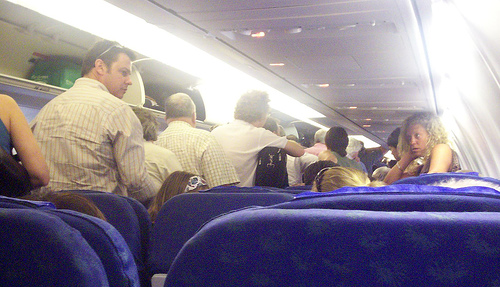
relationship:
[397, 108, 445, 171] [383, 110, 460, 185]
hair on woman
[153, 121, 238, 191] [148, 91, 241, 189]
shirt on passenger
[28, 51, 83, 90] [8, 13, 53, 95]
luggage on compartment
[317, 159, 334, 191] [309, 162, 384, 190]
headband on head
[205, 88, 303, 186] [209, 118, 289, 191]
man wearing white shirt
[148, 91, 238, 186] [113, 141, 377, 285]
passenger standing in aisle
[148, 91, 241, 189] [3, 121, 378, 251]
passenger standing in isle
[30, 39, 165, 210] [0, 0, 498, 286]
man on aircraft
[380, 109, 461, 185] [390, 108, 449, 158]
woman resting her head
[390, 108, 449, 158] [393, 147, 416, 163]
head on hand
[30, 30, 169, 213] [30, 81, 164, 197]
man with shirt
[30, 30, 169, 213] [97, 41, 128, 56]
man with sunglasses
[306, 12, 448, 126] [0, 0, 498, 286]
storage on a aircraft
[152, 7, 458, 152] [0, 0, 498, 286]
compartments on a aircraft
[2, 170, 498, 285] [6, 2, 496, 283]
seats on a airliner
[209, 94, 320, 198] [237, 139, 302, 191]
man with luggage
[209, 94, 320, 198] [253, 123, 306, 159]
man with arm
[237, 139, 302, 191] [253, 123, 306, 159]
luggage under arm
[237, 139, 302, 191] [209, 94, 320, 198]
luggage under man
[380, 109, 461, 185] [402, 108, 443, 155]
woman scratching head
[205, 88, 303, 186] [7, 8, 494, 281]
man exiting aircraft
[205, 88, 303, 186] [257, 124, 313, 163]
man resting arm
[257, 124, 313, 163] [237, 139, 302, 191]
arm on luggage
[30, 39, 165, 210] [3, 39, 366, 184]
man standing in line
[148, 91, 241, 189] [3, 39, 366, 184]
passenger standing in line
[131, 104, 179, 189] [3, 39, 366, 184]
people standing in line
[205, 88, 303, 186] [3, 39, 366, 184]
man standing in line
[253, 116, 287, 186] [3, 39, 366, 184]
people standing in line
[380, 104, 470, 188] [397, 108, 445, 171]
woman with hair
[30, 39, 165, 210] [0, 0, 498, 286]
man getting off aircraft